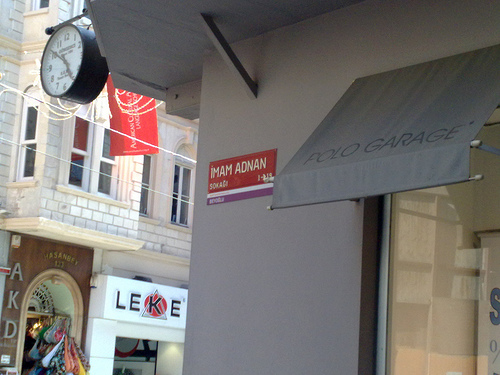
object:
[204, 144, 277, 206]
sign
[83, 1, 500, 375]
building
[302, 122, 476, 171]
logo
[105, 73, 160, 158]
banner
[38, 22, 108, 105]
clock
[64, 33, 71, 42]
number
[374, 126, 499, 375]
window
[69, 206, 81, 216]
brick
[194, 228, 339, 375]
wall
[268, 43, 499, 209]
awning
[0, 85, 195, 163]
lines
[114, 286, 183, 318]
logo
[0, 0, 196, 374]
building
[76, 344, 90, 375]
purses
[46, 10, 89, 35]
pole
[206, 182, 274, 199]
line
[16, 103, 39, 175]
window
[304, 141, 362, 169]
polo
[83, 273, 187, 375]
entrance